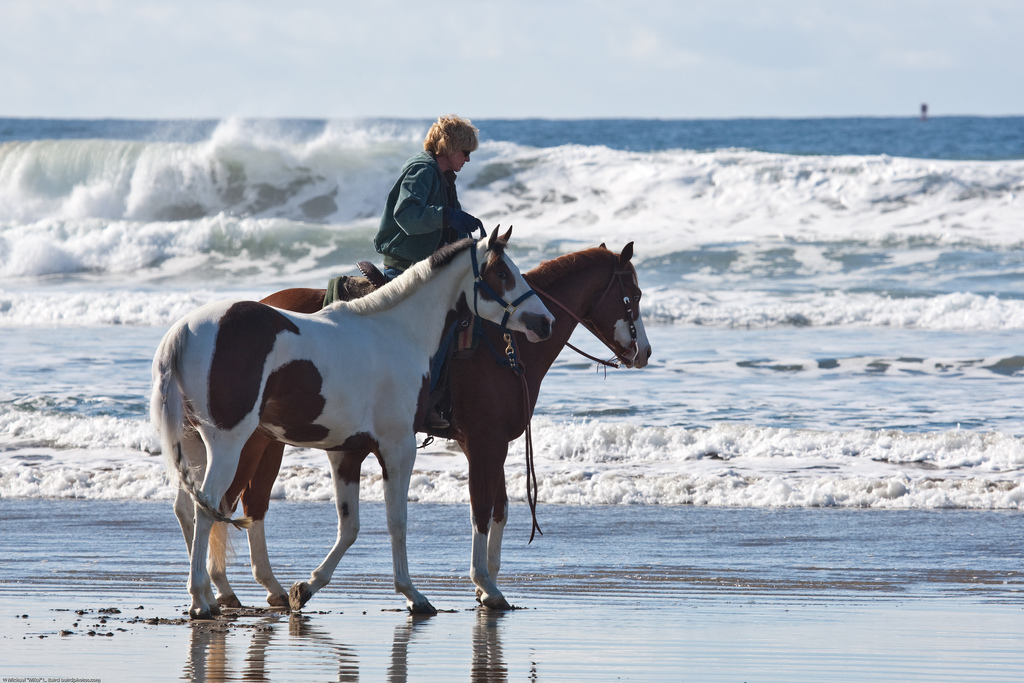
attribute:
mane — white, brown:
[335, 232, 480, 317]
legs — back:
[188, 414, 245, 615]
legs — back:
[211, 434, 294, 616]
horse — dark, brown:
[211, 237, 652, 609]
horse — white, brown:
[153, 224, 562, 622]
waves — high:
[4, 118, 897, 259]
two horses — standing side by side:
[142, 223, 661, 619]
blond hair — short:
[418, 109, 483, 164]